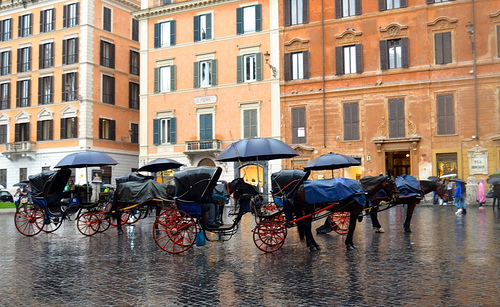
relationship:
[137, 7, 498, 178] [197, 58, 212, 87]
building with window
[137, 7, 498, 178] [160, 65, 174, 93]
building with window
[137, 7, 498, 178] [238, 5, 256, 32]
building with window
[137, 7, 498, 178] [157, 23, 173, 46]
building with window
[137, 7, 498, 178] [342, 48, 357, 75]
building with window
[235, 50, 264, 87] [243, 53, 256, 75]
shutters on window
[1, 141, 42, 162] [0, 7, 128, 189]
balcony at th building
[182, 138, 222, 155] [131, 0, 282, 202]
balcony on building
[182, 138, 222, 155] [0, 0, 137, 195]
balcony on building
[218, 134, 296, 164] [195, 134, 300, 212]
umbrella on a carriage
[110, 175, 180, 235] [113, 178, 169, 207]
horse has raincoat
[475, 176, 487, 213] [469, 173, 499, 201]
person wearing raincoat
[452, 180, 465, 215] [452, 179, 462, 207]
person wearing blue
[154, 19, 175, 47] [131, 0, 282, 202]
window on building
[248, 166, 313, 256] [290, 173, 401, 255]
carriage at end of horse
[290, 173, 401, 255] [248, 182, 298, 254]
horse pulling carriage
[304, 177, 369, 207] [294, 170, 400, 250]
covering on horse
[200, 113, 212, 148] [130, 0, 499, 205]
door to building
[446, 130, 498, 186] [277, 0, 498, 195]
plaque on wall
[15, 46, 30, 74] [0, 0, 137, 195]
window on building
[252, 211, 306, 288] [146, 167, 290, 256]
wheel on carriage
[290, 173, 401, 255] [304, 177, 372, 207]
horse wearing covering